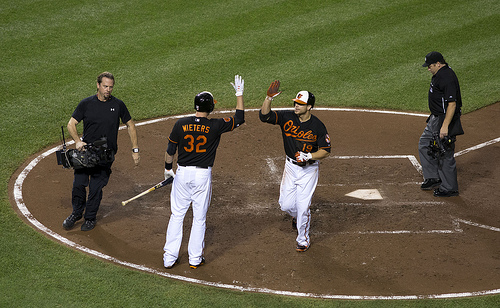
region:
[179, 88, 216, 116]
head of a person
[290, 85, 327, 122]
head of a person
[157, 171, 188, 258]
leg of a person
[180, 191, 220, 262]
leg of a person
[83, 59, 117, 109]
head of a person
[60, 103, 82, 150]
arm of a person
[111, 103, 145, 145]
arm of a person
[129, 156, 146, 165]
hand of a person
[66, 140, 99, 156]
hand of a person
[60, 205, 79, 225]
feet of a person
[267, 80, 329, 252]
player coming home in black Orioles tee shirt and white pants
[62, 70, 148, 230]
camera man on dirt baseball mound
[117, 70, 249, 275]
batter high fiving team plyer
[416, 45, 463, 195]
an umpire looking at ground and carrying mask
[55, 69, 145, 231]
man carrying large camera tv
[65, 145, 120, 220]
black pants on photographer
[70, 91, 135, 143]
black tee- shirt on man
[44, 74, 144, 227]
a camera man standing up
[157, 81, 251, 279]
a batter giving a high five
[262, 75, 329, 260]
a player giving a high five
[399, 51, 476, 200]
an umpire in the middle of walking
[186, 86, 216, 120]
the helmet of a man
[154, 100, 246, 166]
the jersey of a man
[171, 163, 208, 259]
the white pants of a man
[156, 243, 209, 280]
the shoes of an adult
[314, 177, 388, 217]
a white base on a field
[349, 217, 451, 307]
a bit of dirt in a baseball field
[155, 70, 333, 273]
two baseball players hi fiving each other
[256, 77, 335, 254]
baseball player with his hand in the air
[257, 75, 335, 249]
baseball player on a field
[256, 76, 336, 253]
baseball player wearing an orange and black jersey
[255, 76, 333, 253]
baseball player wearing a uniform and gloves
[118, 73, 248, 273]
baseball player wearing a uniform and white gloves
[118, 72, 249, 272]
baseball player holding a baseball bat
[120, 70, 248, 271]
baseball player wearing a jersey with a 32 number print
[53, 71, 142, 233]
cameraman dressed in all black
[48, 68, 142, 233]
cameraman on a baseball field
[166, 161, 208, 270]
baseball player is wearing white pants.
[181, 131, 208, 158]
baseball player has number thirty-two on his shirt.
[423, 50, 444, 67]
man is wearing dark cap.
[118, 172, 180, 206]
man is holding baseball bat.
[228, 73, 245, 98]
man is wearing white batting glove.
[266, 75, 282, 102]
man is wearing red batting glove.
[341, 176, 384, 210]
the base is home plate.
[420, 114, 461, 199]
the man is wearing blue jeans.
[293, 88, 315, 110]
the man is wearing orange, white and black cap.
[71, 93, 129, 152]
man is wearing black shirt.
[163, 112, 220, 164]
man wearing a black jersey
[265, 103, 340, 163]
player wearing a black jersey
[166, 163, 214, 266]
player wearing white pants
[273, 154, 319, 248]
player wearing white pants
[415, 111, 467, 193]
umpire wearing gray pants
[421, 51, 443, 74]
umpire wearing a black hat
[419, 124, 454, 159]
umpire holding a mask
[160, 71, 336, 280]
two baseball player high fiving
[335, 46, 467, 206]
baseball umpire at home plate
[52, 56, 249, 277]
camera man filming baseball player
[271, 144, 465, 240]
chalk lines around home plate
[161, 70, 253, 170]
number thirty two on back of Jerzee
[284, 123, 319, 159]
number nineteen on Jerzee